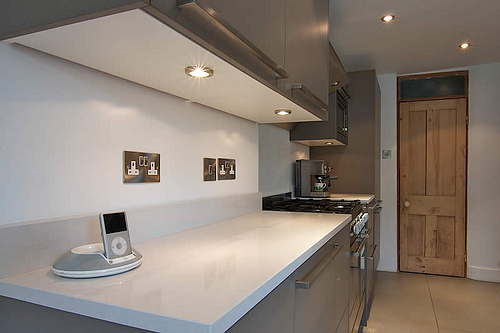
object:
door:
[397, 96, 468, 277]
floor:
[360, 269, 499, 332]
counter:
[0, 192, 352, 331]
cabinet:
[289, 41, 347, 146]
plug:
[127, 160, 141, 176]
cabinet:
[0, 0, 329, 124]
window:
[396, 70, 470, 102]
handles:
[176, 0, 289, 78]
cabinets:
[2, 2, 329, 122]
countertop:
[1, 210, 353, 325]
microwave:
[289, 89, 348, 145]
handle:
[294, 241, 346, 290]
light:
[184, 66, 212, 78]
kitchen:
[0, 0, 498, 332]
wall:
[0, 41, 314, 227]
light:
[380, 13, 394, 22]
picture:
[123, 150, 160, 181]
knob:
[402, 201, 411, 207]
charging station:
[50, 242, 144, 278]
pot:
[312, 175, 328, 192]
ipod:
[99, 210, 131, 259]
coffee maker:
[293, 158, 338, 198]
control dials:
[352, 212, 369, 235]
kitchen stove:
[262, 197, 360, 213]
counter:
[290, 193, 377, 203]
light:
[274, 109, 292, 115]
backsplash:
[0, 192, 263, 279]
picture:
[203, 157, 216, 181]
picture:
[218, 158, 236, 180]